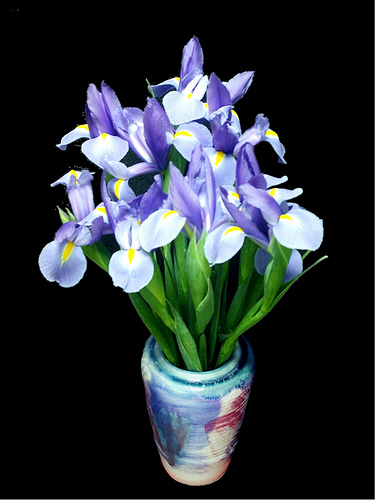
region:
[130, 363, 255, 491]
A flower pot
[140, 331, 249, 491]
Flower pot is colorful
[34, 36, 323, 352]
Very beautiful flowers in the pot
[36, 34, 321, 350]
The flowers are mainly purple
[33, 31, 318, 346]
The flower petals have some yellow inside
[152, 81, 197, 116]
Heart shaped flower petal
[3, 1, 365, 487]
The background is black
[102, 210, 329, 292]
white looking flower petals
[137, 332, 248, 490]
The flower pot has blue, pink, and purple colors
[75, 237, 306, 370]
Flower stems are green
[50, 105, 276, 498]
flowers in a vase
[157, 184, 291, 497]
flowers in a vase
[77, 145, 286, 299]
the flowers are purple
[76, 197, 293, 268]
the flowers are purple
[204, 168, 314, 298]
the flowers are purple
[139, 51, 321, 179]
the flowers are purple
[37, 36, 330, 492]
purple flowers in jar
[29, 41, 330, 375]
purple irises with stems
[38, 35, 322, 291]
purple flowers with yellow and white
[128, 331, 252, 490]
ceramic vase with glaze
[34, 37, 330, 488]
ceramic vase containing flowers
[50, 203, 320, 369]
bright green flower stems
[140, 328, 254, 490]
multi colored ceramic vase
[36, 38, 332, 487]
spring flowers in vase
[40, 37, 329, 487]
fresh flowers in vase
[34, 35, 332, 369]
purple flowers with yellow centers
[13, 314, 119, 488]
The canvas is black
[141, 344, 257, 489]
The vase is multi colored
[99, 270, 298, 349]
The flower stems are green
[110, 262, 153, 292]
The outer part of the flower is white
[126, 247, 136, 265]
The middle part of the flower is yellow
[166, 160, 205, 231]
The upper part of the flower is lilac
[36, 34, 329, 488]
There are lilac flowers in a vase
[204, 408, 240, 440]
The plum color is on the vase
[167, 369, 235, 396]
The blue color is on the vase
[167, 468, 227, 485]
The pink color in on the bottom of the vase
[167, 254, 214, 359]
the stem is green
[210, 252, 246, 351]
the stem is green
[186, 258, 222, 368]
the stem is green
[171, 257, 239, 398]
the stem is green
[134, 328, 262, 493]
the vase is colorful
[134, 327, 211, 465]
the vase is colorful